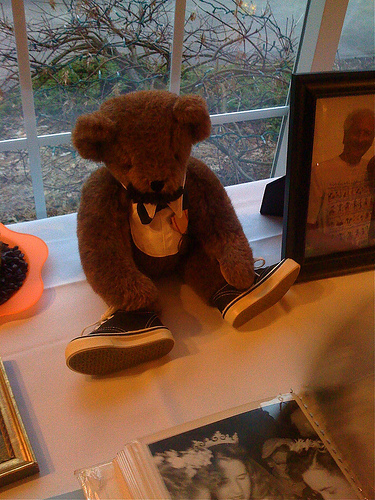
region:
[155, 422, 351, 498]
Photo of women at a wedding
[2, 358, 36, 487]
Edge of gold picture frame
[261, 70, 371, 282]
Photo in a standing frame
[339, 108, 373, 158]
Photo of man with gray hair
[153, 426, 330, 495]
Photo of women wearing tiaras and flowers in hair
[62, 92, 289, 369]
Brown stuffed teddy bear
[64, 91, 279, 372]
Stuffed bear wearing sneakers and tuxedo bib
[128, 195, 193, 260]
White tuxedo bib with black bow and pink pocket kerchief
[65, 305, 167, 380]
Black canvas sneaker with white sole and laces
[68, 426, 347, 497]
Open photo album on table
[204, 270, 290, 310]
the bear is wearing shoes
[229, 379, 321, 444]
the album is sitting on the table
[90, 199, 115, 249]
the bear is brown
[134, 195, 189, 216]
the bear is wearing a bow tie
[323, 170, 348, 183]
the shirt is white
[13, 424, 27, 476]
the frame is gold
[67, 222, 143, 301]
the bear is sitting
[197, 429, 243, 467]
the lady is wearing a tiara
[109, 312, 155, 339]
the shoes are blue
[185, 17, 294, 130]
the window has no curtains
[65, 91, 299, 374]
A brown teddy bear wearing canvas shoes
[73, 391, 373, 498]
Picture frame lying on the table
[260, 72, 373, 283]
Standing picture frame of a man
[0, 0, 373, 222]
Glass panel of the window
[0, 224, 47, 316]
Half of a Papaya fruit showing black seeds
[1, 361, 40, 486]
Small part visible of another picture frame on table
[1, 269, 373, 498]
Brown tabletop near the window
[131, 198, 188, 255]
Bib on the teddy bear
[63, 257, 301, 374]
Blue canvas shoes of the teddy bear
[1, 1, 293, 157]
Green string lights on brown leafless tree branches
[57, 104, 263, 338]
a brown teddy bear siiting on a table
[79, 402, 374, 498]
a black and white picture in a stack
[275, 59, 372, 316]
a framed photo on a table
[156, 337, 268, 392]
white surface of the table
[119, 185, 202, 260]
the bear's white bib and bow tie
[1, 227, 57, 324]
an orange bow filled with black stones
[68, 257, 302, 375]
the bear's black and white tennis shoes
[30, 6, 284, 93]
a tree covered in christmas lights outside the window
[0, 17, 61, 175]
white framing of the window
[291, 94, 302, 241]
brown wooden frame of the photo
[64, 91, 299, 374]
the teddy bear sitting down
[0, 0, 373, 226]
the window behind the teddy bear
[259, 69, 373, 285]
the frame next to the teddy bear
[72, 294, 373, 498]
the photo album in front of the bear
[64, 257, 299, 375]
the shoes on the bear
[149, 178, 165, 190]
the nose on the bear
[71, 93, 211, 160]
the ears on the bear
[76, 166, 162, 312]
the arm on the bear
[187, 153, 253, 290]
the arm on the bear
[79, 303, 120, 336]
the laces on the shoe